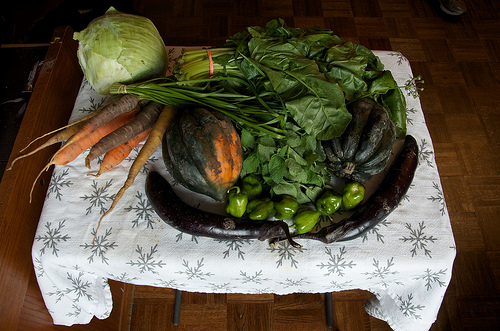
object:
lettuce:
[71, 6, 166, 99]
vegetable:
[143, 110, 415, 243]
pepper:
[344, 180, 366, 208]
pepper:
[314, 193, 346, 217]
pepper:
[293, 207, 321, 235]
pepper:
[246, 201, 273, 218]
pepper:
[227, 182, 249, 216]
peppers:
[340, 180, 366, 211]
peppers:
[246, 194, 275, 220]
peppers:
[268, 192, 300, 224]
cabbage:
[68, 8, 170, 92]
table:
[4, 12, 498, 324]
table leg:
[164, 287, 191, 327]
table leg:
[314, 290, 340, 327]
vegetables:
[0, 16, 421, 241]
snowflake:
[126, 238, 166, 276]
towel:
[338, 222, 479, 329]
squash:
[157, 97, 239, 209]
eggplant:
[322, 139, 419, 248]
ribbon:
[203, 48, 215, 77]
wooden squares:
[0, 9, 500, 330]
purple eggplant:
[137, 170, 292, 245]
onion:
[105, 72, 295, 137]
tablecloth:
[31, 50, 457, 330]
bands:
[114, 80, 126, 95]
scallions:
[104, 72, 295, 136]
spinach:
[169, 14, 398, 141]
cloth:
[29, 47, 455, 330]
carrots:
[12, 92, 170, 223]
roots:
[70, 184, 131, 244]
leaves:
[232, 9, 391, 198]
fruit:
[16, 5, 420, 250]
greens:
[111, 19, 405, 238]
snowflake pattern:
[66, 222, 126, 271]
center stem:
[260, 53, 336, 132]